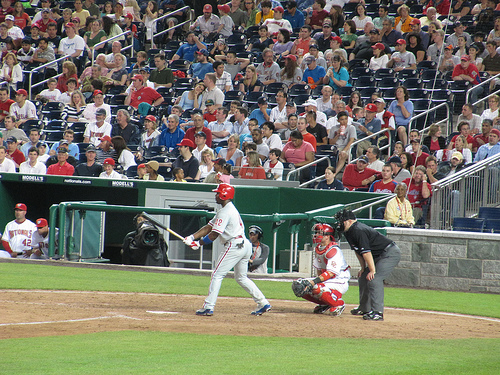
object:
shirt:
[282, 140, 315, 162]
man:
[248, 96, 271, 125]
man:
[159, 114, 187, 148]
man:
[302, 57, 326, 86]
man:
[238, 118, 259, 150]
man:
[19, 129, 50, 158]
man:
[49, 129, 80, 160]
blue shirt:
[302, 65, 327, 84]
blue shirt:
[159, 126, 185, 148]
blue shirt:
[176, 42, 208, 63]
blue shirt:
[282, 8, 305, 28]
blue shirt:
[327, 67, 353, 89]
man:
[384, 182, 417, 228]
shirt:
[384, 196, 416, 224]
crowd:
[0, 0, 500, 202]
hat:
[176, 138, 195, 148]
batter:
[182, 183, 272, 316]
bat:
[140, 211, 184, 240]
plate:
[146, 310, 184, 317]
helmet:
[212, 183, 235, 200]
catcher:
[291, 222, 352, 318]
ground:
[0, 260, 499, 374]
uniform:
[201, 200, 267, 309]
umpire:
[331, 205, 411, 337]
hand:
[366, 270, 376, 280]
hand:
[357, 268, 364, 277]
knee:
[366, 274, 376, 284]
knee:
[358, 273, 364, 282]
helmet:
[314, 223, 336, 242]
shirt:
[343, 220, 394, 260]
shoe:
[250, 302, 272, 316]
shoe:
[362, 310, 384, 322]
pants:
[333, 208, 402, 321]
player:
[0, 206, 38, 261]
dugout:
[1, 176, 393, 284]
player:
[30, 218, 59, 259]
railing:
[429, 153, 500, 230]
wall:
[373, 227, 500, 294]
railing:
[29, 54, 73, 99]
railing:
[91, 29, 133, 67]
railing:
[150, 4, 193, 50]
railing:
[285, 156, 333, 188]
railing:
[346, 128, 391, 164]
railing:
[408, 102, 449, 145]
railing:
[465, 74, 500, 106]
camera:
[134, 219, 160, 249]